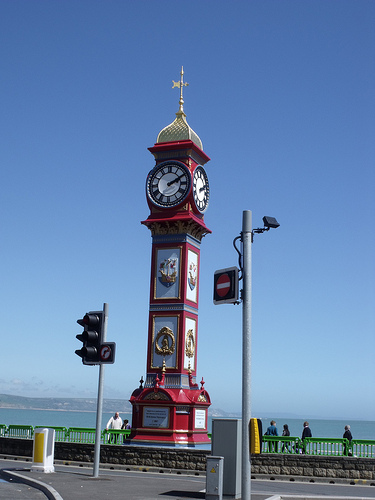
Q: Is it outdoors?
A: Yes, it is outdoors.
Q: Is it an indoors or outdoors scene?
A: It is outdoors.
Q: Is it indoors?
A: No, it is outdoors.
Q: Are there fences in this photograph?
A: Yes, there is a fence.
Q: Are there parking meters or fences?
A: Yes, there is a fence.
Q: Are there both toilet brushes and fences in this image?
A: No, there is a fence but no toilet brushes.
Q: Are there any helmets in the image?
A: No, there are no helmets.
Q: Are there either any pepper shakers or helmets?
A: No, there are no helmets or pepper shakers.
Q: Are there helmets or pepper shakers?
A: No, there are no helmets or pepper shakers.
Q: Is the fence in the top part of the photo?
A: No, the fence is in the bottom of the image.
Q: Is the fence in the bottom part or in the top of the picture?
A: The fence is in the bottom of the image.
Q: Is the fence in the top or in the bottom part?
A: The fence is in the bottom of the image.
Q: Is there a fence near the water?
A: Yes, there is a fence near the water.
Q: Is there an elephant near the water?
A: No, there is a fence near the water.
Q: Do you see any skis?
A: No, there are no skis.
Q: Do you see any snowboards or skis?
A: No, there are no skis or snowboards.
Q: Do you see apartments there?
A: No, there are no apartments.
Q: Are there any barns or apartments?
A: No, there are no apartments or barns.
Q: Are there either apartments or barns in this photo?
A: No, there are no apartments or barns.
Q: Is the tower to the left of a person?
A: Yes, the tower is to the left of a person.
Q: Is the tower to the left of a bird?
A: No, the tower is to the left of a person.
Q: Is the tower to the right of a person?
A: No, the tower is to the left of a person.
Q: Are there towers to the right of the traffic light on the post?
A: Yes, there is a tower to the right of the traffic light.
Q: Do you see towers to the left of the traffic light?
A: No, the tower is to the right of the traffic light.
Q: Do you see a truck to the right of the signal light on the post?
A: No, there is a tower to the right of the traffic light.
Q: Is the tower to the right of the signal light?
A: Yes, the tower is to the right of the signal light.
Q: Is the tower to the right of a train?
A: No, the tower is to the right of the signal light.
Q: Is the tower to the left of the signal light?
A: No, the tower is to the right of the signal light.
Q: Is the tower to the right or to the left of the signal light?
A: The tower is to the right of the signal light.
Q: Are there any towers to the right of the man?
A: Yes, there is a tower to the right of the man.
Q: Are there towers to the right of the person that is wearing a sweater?
A: Yes, there is a tower to the right of the man.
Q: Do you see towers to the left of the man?
A: No, the tower is to the right of the man.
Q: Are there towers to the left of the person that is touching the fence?
A: No, the tower is to the right of the man.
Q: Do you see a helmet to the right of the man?
A: No, there is a tower to the right of the man.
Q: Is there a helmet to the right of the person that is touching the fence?
A: No, there is a tower to the right of the man.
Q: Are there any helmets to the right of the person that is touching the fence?
A: No, there is a tower to the right of the man.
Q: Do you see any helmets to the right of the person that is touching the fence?
A: No, there is a tower to the right of the man.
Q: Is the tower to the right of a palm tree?
A: No, the tower is to the right of a man.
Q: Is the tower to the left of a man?
A: No, the tower is to the right of a man.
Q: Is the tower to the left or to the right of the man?
A: The tower is to the right of the man.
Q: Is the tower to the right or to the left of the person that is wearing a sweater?
A: The tower is to the right of the man.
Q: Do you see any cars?
A: No, there are no cars.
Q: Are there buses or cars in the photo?
A: No, there are no cars or buses.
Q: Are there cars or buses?
A: No, there are no cars or buses.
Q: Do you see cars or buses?
A: No, there are no cars or buses.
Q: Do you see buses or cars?
A: No, there are no cars or buses.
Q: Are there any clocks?
A: Yes, there is a clock.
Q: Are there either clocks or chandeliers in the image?
A: Yes, there is a clock.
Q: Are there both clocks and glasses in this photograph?
A: No, there is a clock but no glasses.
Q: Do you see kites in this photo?
A: No, there are no kites.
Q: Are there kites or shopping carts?
A: No, there are no kites or shopping carts.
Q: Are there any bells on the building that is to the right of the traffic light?
A: No, there is a clock on the tower.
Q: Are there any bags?
A: No, there are no bags.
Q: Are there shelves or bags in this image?
A: No, there are no bags or shelves.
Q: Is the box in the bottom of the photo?
A: Yes, the box is in the bottom of the image.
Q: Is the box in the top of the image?
A: No, the box is in the bottom of the image.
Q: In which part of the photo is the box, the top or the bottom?
A: The box is in the bottom of the image.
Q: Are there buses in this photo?
A: No, there are no buses.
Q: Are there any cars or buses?
A: No, there are no buses or cars.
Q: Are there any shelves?
A: No, there are no shelves.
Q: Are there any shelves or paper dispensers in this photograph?
A: No, there are no shelves or paper dispensers.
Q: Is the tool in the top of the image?
A: Yes, the tool is in the top of the image.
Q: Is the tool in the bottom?
A: No, the tool is in the top of the image.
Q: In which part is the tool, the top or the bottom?
A: The tool is in the top of the image.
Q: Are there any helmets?
A: No, there are no helmets.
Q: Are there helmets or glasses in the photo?
A: No, there are no helmets or glasses.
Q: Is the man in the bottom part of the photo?
A: Yes, the man is in the bottom of the image.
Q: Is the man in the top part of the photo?
A: No, the man is in the bottom of the image.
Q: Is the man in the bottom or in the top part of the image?
A: The man is in the bottom of the image.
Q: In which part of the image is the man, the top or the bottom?
A: The man is in the bottom of the image.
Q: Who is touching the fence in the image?
A: The man is touching the fence.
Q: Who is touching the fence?
A: The man is touching the fence.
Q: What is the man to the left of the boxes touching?
A: The man is touching the fence.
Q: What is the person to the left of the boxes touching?
A: The man is touching the fence.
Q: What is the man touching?
A: The man is touching the fence.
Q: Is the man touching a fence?
A: Yes, the man is touching a fence.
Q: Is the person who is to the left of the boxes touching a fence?
A: Yes, the man is touching a fence.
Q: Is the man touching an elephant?
A: No, the man is touching a fence.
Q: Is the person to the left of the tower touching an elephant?
A: No, the man is touching a fence.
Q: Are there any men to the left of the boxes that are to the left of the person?
A: Yes, there is a man to the left of the boxes.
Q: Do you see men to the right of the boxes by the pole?
A: No, the man is to the left of the boxes.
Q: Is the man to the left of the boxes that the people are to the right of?
A: Yes, the man is to the left of the boxes.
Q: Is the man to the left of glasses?
A: No, the man is to the left of the boxes.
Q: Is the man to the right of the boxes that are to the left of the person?
A: No, the man is to the left of the boxes.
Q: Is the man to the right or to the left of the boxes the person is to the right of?
A: The man is to the left of the boxes.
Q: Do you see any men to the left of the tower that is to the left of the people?
A: Yes, there is a man to the left of the tower.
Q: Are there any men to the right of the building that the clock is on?
A: No, the man is to the left of the tower.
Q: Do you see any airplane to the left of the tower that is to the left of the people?
A: No, there is a man to the left of the tower.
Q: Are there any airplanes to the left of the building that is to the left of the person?
A: No, there is a man to the left of the tower.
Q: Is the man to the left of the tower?
A: Yes, the man is to the left of the tower.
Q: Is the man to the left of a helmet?
A: No, the man is to the left of the tower.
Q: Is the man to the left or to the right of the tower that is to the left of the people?
A: The man is to the left of the tower.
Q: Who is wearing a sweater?
A: The man is wearing a sweater.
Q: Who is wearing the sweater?
A: The man is wearing a sweater.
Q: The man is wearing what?
A: The man is wearing a sweater.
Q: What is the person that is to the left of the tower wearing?
A: The man is wearing a sweater.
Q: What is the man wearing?
A: The man is wearing a sweater.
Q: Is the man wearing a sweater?
A: Yes, the man is wearing a sweater.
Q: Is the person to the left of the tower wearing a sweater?
A: Yes, the man is wearing a sweater.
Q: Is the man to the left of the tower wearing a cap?
A: No, the man is wearing a sweater.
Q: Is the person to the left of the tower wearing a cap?
A: No, the man is wearing a sweater.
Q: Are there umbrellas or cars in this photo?
A: No, there are no cars or umbrellas.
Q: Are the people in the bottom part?
A: Yes, the people are in the bottom of the image.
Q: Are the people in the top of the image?
A: No, the people are in the bottom of the image.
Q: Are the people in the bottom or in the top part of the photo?
A: The people are in the bottom of the image.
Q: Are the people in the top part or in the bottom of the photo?
A: The people are in the bottom of the image.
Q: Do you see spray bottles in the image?
A: No, there are no spray bottles.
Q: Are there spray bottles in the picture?
A: No, there are no spray bottles.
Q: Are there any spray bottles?
A: No, there are no spray bottles.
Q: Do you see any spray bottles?
A: No, there are no spray bottles.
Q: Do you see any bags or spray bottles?
A: No, there are no spray bottles or bags.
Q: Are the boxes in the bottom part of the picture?
A: Yes, the boxes are in the bottom of the image.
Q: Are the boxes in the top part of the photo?
A: No, the boxes are in the bottom of the image.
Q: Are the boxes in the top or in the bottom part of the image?
A: The boxes are in the bottom of the image.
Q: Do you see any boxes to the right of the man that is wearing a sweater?
A: Yes, there are boxes to the right of the man.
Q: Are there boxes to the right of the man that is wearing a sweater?
A: Yes, there are boxes to the right of the man.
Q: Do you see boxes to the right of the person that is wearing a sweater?
A: Yes, there are boxes to the right of the man.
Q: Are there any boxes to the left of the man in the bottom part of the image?
A: No, the boxes are to the right of the man.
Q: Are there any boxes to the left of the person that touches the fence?
A: No, the boxes are to the right of the man.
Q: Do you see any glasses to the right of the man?
A: No, there are boxes to the right of the man.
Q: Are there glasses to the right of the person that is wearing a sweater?
A: No, there are boxes to the right of the man.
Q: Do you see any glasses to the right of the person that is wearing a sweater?
A: No, there are boxes to the right of the man.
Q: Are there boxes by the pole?
A: Yes, there are boxes by the pole.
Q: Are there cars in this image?
A: No, there are no cars.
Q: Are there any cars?
A: No, there are no cars.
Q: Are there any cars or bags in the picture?
A: No, there are no cars or bags.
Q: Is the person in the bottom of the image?
A: Yes, the person is in the bottom of the image.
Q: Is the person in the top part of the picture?
A: No, the person is in the bottom of the image.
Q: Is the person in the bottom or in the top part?
A: The person is in the bottom of the image.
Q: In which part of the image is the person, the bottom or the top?
A: The person is in the bottom of the image.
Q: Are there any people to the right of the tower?
A: Yes, there is a person to the right of the tower.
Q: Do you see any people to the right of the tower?
A: Yes, there is a person to the right of the tower.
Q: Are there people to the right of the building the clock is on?
A: Yes, there is a person to the right of the tower.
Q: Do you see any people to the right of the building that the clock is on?
A: Yes, there is a person to the right of the tower.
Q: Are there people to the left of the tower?
A: No, the person is to the right of the tower.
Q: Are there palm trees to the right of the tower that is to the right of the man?
A: No, there is a person to the right of the tower.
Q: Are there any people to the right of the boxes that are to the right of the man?
A: Yes, there is a person to the right of the boxes.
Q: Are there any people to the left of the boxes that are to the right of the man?
A: No, the person is to the right of the boxes.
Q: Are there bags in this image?
A: No, there are no bags.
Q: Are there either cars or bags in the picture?
A: No, there are no bags or cars.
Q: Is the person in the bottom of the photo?
A: Yes, the person is in the bottom of the image.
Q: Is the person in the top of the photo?
A: No, the person is in the bottom of the image.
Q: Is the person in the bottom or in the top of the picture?
A: The person is in the bottom of the image.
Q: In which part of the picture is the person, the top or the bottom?
A: The person is in the bottom of the image.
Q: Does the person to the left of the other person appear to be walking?
A: Yes, the person is walking.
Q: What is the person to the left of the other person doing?
A: The person is walking.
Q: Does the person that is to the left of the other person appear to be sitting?
A: No, the person is walking.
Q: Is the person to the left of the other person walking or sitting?
A: The person is walking.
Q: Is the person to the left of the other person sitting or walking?
A: The person is walking.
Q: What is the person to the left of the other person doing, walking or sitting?
A: The person is walking.